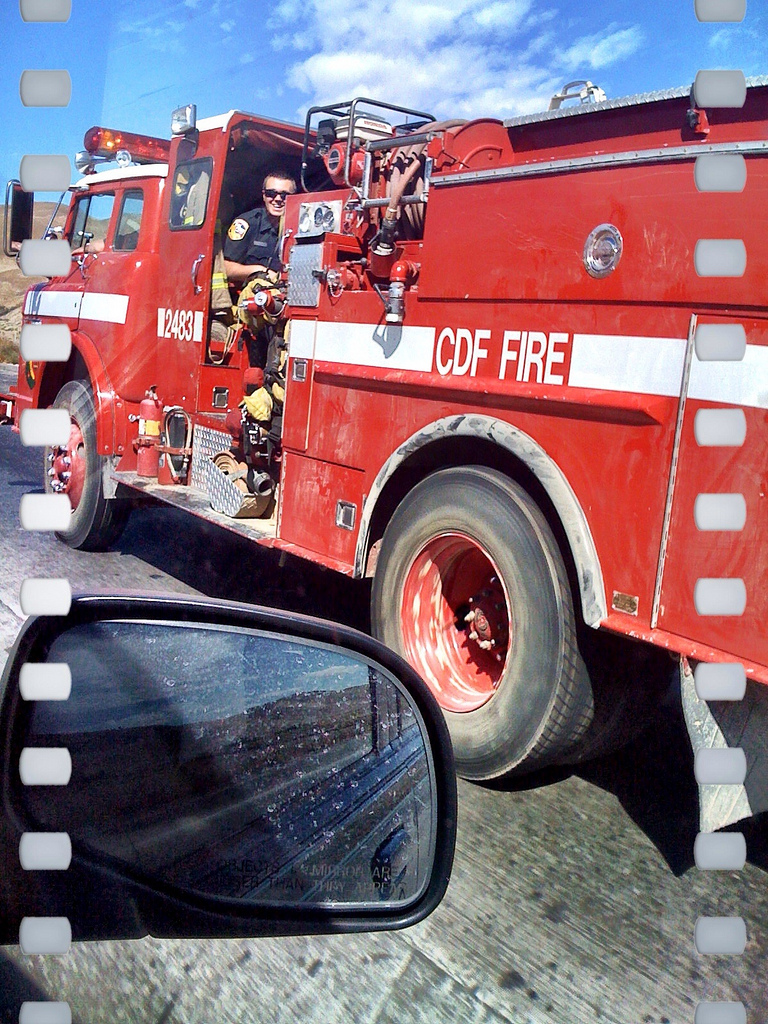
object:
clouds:
[408, 6, 427, 46]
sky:
[0, 0, 768, 223]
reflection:
[25, 618, 435, 906]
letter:
[543, 330, 570, 385]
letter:
[516, 331, 528, 382]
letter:
[185, 310, 194, 342]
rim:
[397, 527, 514, 715]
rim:
[45, 413, 87, 515]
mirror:
[0, 588, 464, 950]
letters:
[497, 329, 523, 381]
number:
[164, 307, 194, 343]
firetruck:
[0, 60, 768, 791]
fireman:
[222, 169, 297, 302]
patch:
[227, 216, 251, 241]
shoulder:
[224, 206, 263, 256]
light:
[82, 124, 171, 165]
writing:
[434, 325, 570, 384]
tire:
[366, 460, 600, 788]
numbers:
[163, 307, 173, 339]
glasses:
[264, 188, 292, 200]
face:
[261, 174, 297, 217]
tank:
[582, 221, 625, 280]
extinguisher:
[131, 382, 194, 487]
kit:
[190, 384, 277, 519]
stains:
[512, 927, 528, 950]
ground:
[0, 474, 768, 1023]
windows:
[112, 186, 145, 252]